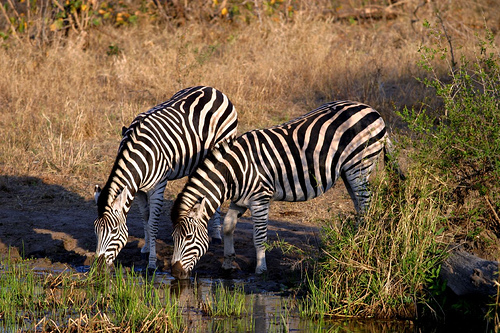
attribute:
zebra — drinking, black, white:
[171, 102, 422, 279]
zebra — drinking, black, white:
[93, 85, 243, 275]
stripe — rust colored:
[339, 119, 384, 164]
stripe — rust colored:
[220, 110, 237, 135]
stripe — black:
[332, 110, 381, 185]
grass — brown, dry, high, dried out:
[0, 6, 496, 193]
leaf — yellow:
[219, 8, 229, 17]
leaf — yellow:
[95, 9, 106, 16]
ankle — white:
[256, 250, 267, 277]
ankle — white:
[148, 245, 159, 263]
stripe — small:
[253, 208, 268, 214]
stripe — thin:
[254, 238, 267, 244]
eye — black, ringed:
[185, 235, 194, 243]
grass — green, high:
[5, 247, 182, 332]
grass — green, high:
[200, 279, 249, 317]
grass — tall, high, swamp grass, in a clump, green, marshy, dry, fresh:
[267, 143, 450, 320]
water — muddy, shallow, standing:
[0, 260, 500, 331]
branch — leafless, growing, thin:
[430, 3, 459, 76]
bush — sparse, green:
[386, 2, 499, 259]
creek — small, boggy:
[0, 267, 497, 331]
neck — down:
[107, 142, 143, 211]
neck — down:
[177, 164, 228, 218]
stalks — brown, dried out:
[33, 312, 118, 332]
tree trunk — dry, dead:
[436, 242, 499, 298]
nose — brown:
[170, 262, 185, 277]